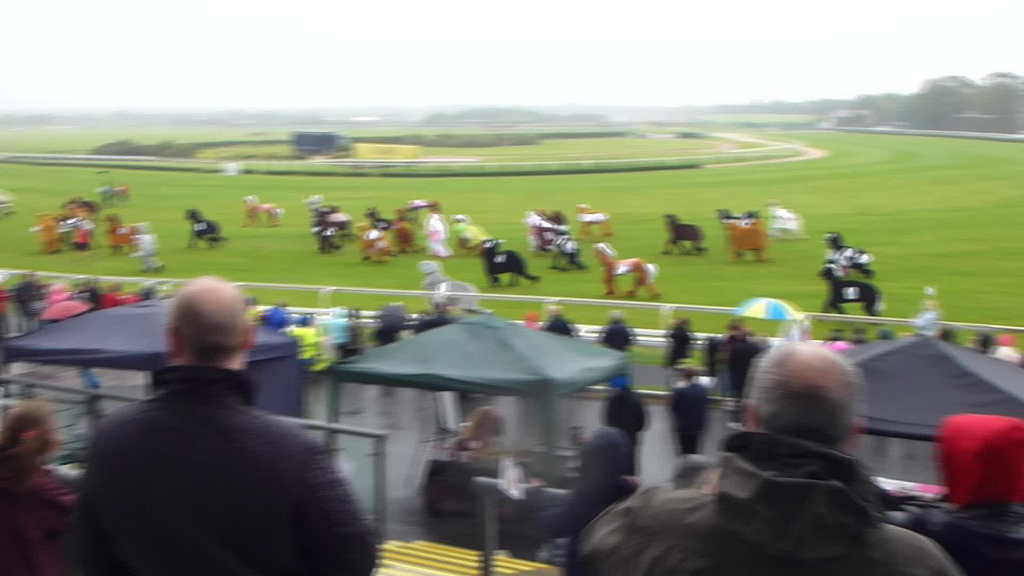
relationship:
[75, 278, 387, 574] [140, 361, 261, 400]
man has collar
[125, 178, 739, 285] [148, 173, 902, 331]
horses on grass